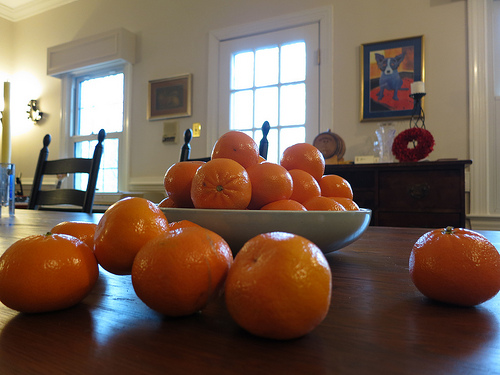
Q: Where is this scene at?
A: Dining room.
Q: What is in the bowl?
A: Oranges.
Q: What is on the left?
A: Chair.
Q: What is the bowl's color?
A: White.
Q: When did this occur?
A: During the day time.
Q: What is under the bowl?
A: Table.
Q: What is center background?
A: Door.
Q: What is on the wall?
A: Pictures.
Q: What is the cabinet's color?
A: Brown.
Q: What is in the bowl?
A: Oranges.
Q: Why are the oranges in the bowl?
A: For decoration.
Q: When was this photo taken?
A: During the day.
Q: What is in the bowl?
A: Oranges.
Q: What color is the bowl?
A: White.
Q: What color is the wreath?
A: Red.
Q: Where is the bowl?
A: On a table.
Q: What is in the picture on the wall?
A: A dog.